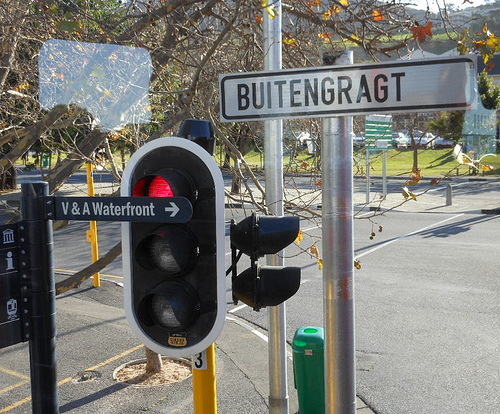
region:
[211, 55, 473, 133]
Black and white street sign.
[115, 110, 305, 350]
Stop lights at street corner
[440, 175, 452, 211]
Road barricaded in crosswalk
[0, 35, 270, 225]
Tree with few leaves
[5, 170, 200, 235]
Sign with direction to waterfront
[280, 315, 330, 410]
Green trash can on curb.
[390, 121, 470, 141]
Parked cars across the street.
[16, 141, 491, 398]
Black top road way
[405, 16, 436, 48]
Orange leaf on branch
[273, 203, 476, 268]
Crosswalk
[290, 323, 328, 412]
green box near curb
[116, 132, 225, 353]
traffic signal with red light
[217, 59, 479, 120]
black and white sign for Buitengragt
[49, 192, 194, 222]
blue and white street sign with arrow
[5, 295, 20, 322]
train icon on sign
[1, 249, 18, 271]
information icon on sign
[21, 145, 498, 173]
grassy area across street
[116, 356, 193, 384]
bark mulch around base of tree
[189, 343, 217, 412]
yellow metal pole with number 3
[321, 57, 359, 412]
metal pole supporting Buitengragt sign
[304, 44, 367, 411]
a gray metal pole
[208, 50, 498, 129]
a black and white street sign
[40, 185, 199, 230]
a black street sign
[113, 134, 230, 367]
a bank of traffic lights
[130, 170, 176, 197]
a red traffic light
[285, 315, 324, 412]
a green plastic bin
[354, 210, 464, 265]
a white line on the ground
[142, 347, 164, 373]
a brown tree trunk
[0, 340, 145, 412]
a yellow line on the ground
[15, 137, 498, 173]
a patch of green grass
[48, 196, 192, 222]
black sign with V & A Waterfront in white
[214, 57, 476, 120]
white sign with Buitengragt in black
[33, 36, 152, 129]
reflection of sign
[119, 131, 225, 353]
black box with red light on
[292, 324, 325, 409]
green box on sidewalk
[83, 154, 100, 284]
tall skinny yellow sign pole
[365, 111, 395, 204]
green street sign with two metal legs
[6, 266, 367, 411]
corner sidewalk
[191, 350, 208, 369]
black three on yellow pole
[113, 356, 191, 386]
circular indent in pavement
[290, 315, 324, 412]
Green trash can next to silver pole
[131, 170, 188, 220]
Light is red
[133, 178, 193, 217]
Red light obstructed by street sign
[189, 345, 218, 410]
Pole is yellow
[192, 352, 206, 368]
Number 3 on yellow pole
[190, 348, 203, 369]
Number 3 is black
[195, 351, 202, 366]
Number 3 on white sticker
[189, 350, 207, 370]
White sticker on yellow pole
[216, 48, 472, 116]
Black and white sign on metal pole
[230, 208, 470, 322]
White traffic line on road